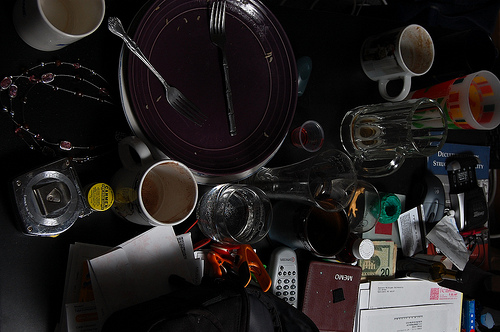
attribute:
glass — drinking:
[192, 177, 277, 249]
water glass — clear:
[196, 183, 275, 248]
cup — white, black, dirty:
[358, 20, 438, 110]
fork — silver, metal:
[205, 5, 250, 143]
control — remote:
[272, 241, 304, 308]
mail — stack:
[364, 282, 480, 327]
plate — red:
[103, 16, 329, 173]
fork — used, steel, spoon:
[103, 17, 220, 152]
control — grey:
[268, 250, 306, 318]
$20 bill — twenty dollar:
[360, 242, 394, 278]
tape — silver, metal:
[18, 169, 100, 233]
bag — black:
[224, 257, 315, 326]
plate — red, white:
[130, 76, 282, 194]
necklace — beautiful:
[0, 50, 117, 163]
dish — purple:
[115, 2, 298, 188]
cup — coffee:
[118, 137, 194, 229]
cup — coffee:
[365, 26, 436, 98]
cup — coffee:
[25, 3, 107, 50]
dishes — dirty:
[115, 119, 326, 276]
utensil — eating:
[105, 15, 210, 131]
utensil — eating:
[209, 0, 239, 137]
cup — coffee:
[123, 154, 200, 234]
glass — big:
[333, 90, 453, 180]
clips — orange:
[204, 243, 273, 290]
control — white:
[274, 240, 319, 294]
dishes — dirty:
[348, 19, 482, 144]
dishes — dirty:
[15, 2, 301, 103]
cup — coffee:
[355, 15, 437, 104]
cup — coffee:
[12, 2, 115, 52]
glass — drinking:
[254, 148, 356, 215]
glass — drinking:
[325, 170, 383, 238]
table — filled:
[7, 3, 474, 324]